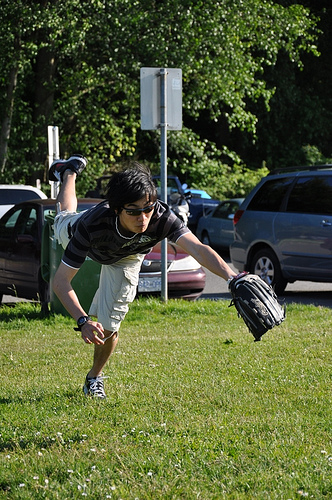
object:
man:
[45, 154, 283, 398]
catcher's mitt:
[227, 269, 285, 342]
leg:
[55, 171, 84, 248]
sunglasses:
[121, 204, 154, 217]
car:
[0, 199, 205, 303]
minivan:
[229, 166, 331, 293]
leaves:
[226, 101, 232, 110]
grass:
[0, 293, 331, 500]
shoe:
[44, 155, 86, 182]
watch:
[73, 314, 90, 331]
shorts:
[54, 210, 146, 343]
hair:
[106, 162, 155, 217]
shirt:
[61, 200, 191, 270]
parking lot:
[0, 163, 331, 306]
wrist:
[73, 309, 90, 330]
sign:
[140, 66, 182, 131]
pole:
[158, 67, 168, 303]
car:
[195, 197, 245, 252]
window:
[280, 175, 332, 216]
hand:
[80, 317, 105, 346]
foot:
[45, 155, 87, 178]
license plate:
[138, 275, 162, 291]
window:
[1, 207, 22, 239]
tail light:
[233, 208, 244, 223]